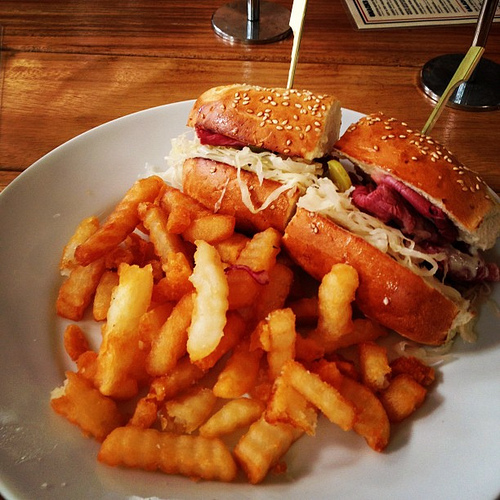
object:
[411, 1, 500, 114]
stick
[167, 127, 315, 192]
sauerkraut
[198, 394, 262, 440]
cut fry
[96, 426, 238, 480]
cut fry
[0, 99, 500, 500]
white plate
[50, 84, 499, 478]
food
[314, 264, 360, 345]
cut frie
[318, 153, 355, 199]
pickle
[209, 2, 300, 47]
silver base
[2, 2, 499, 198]
table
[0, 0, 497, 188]
board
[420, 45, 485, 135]
toothpick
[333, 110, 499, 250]
bun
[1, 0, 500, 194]
wooden table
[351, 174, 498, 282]
beef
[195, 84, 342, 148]
seeds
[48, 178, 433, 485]
crinkled fries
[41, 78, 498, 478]
sandwich/fries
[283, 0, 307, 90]
toothpick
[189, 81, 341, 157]
bun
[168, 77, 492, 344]
reuben sandwich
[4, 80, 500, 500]
plate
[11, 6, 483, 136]
grain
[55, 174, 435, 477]
french fries